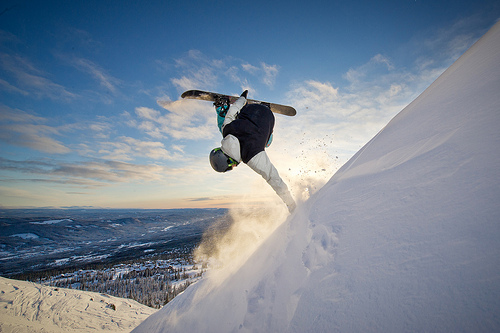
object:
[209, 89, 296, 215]
person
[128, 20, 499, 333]
hill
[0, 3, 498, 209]
sky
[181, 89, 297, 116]
board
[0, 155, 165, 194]
cloud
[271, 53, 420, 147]
cloud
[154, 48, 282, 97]
cloud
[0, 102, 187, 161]
cloud